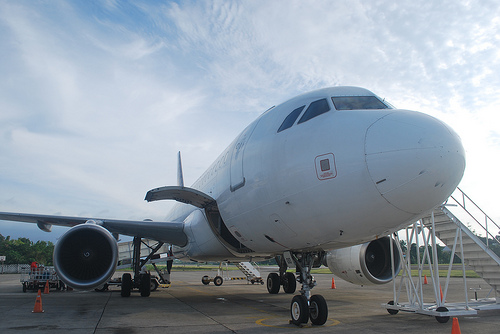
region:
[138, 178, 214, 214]
open door of a plane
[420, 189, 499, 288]
stairs leading to a plane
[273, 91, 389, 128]
cockpit of the plane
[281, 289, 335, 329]
front landing gear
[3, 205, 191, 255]
right wing of the plane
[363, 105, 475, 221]
nose of the plane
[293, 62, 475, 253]
nose of the plane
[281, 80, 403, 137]
window on front of plane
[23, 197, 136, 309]
engine of the plane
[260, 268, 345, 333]
wheels under the plane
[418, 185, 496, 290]
stairs next to plane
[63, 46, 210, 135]
sky above the land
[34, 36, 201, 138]
clouds in the sky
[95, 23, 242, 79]
blue sky above the land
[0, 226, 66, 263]
trees in the distance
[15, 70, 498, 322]
a parked jumbo jet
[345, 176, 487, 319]
a portable staircase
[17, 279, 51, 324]
an orange traffic cone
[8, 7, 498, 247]
a light blue sky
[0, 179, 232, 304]
a plane's right wing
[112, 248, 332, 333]
a jet's landing gear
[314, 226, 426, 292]
an airplane's left jet engine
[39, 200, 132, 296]
an airplane's right jet engine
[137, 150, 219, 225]
an open cargo hold door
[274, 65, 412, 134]
an airplane's windshield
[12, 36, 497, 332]
this is a plane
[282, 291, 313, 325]
this is a tyre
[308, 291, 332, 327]
this is a tyre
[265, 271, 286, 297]
this is a tyre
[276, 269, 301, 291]
this is a tyre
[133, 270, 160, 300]
this is a tyre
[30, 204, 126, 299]
an engine of a plane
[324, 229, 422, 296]
an engine of a plane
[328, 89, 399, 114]
this is a window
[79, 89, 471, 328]
white plane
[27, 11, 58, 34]
white clouds in blue sky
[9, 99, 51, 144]
white clouds in blue sky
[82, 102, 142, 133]
white clouds in blue sky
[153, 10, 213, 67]
white clouds in blue sky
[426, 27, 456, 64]
white clouds in blue sky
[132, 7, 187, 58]
white clouds in blue sky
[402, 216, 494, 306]
the stairs are white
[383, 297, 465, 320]
the wheels are black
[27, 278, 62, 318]
cones on the pavement